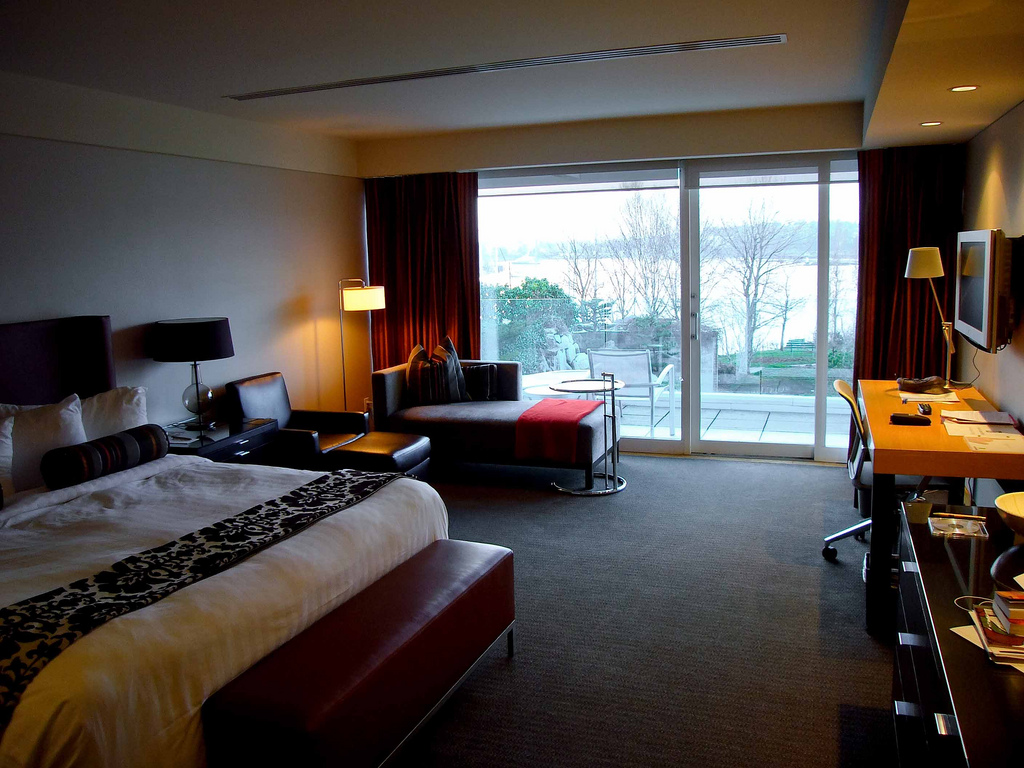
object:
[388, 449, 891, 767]
carpet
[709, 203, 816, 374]
trees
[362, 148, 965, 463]
window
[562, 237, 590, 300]
branch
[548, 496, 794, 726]
floor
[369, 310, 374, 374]
pole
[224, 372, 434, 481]
chair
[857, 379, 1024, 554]
desk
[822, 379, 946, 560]
chair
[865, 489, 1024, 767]
chest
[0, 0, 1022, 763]
room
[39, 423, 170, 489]
pillow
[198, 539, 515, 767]
bench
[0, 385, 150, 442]
pillows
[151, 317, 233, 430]
table lamp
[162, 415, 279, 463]
table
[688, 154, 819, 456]
door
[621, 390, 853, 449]
patio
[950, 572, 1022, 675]
literature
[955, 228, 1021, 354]
television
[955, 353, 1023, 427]
wall